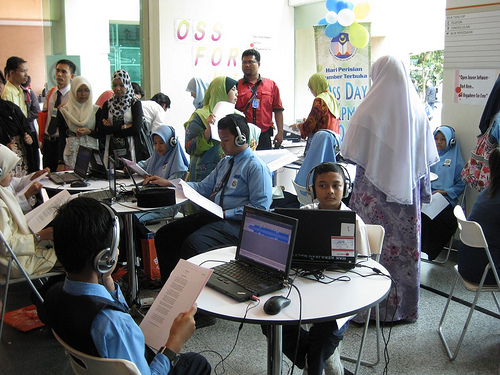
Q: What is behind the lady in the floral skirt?
A: A white chair.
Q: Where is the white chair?
A: On the floor.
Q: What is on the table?
A: A black laptop.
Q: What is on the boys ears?
A: Headphones.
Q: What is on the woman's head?
A: A white head cover.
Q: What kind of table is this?
A: A round table.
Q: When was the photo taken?
A: During the daytime.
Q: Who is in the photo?
A: Some kids and adults.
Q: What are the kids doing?
A: Listening.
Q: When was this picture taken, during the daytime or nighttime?
A: Daytime.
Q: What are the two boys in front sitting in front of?
A: Laptops.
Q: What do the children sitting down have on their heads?
A: Headphones.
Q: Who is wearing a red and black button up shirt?
A: A man.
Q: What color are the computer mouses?
A: Black.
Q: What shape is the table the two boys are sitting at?
A: Circle.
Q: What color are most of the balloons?
A: Blue.